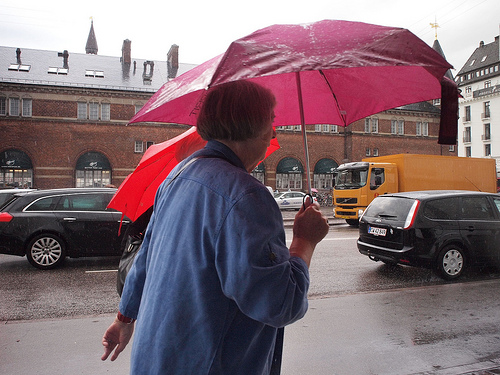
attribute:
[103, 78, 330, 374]
person — walking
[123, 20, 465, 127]
umbrella — red, wet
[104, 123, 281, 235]
umbrella — red, wet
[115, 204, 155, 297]
person — walking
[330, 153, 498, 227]
truck — yellow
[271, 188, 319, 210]
car — white, parked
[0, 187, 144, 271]
car — black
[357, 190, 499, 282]
car — black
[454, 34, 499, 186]
building — white, brick, tall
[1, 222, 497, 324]
road — grey, soaked, dark, wet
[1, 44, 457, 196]
building — red, brick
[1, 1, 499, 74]
sky — grey, rainy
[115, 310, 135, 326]
watch — red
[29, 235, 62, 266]
rims — silver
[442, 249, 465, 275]
rims — silver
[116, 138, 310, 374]
shirt — blue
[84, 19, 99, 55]
steeple — pointed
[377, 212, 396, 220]
wiper — black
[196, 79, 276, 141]
hair — short